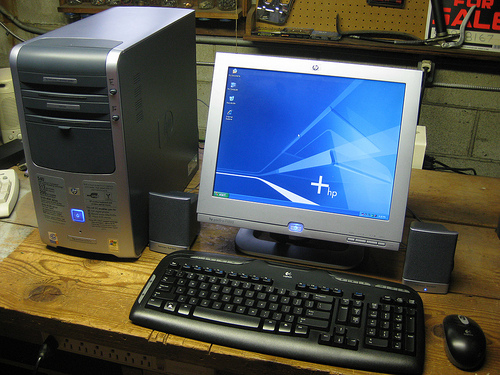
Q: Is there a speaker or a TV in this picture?
A: Yes, there is a speaker.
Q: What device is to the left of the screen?
A: The device is a speaker.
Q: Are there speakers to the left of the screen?
A: Yes, there is a speaker to the left of the screen.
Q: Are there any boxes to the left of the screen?
A: No, there is a speaker to the left of the screen.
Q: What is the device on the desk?
A: The device is a speaker.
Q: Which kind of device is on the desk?
A: The device is a speaker.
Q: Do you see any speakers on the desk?
A: Yes, there is a speaker on the desk.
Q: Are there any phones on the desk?
A: No, there is a speaker on the desk.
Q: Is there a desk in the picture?
A: Yes, there is a desk.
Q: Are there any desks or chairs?
A: Yes, there is a desk.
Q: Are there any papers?
A: No, there are no papers.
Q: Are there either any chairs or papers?
A: No, there are no papers or chairs.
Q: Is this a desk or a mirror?
A: This is a desk.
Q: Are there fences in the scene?
A: No, there are no fences.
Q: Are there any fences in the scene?
A: No, there are no fences.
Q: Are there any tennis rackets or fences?
A: No, there are no fences or tennis rackets.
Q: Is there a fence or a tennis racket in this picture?
A: No, there are no fences or rackets.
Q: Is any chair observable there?
A: No, there are no chairs.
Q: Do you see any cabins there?
A: No, there are no cabins.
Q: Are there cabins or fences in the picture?
A: No, there are no cabins or fences.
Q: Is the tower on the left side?
A: Yes, the tower is on the left of the image.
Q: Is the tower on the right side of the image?
A: No, the tower is on the left of the image.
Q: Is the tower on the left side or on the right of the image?
A: The tower is on the left of the image.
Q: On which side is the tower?
A: The tower is on the left of the image.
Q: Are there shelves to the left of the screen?
A: No, there is a tower to the left of the screen.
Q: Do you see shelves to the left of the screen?
A: No, there is a tower to the left of the screen.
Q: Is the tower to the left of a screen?
A: Yes, the tower is to the left of a screen.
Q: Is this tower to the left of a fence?
A: No, the tower is to the left of a screen.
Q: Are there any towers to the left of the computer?
A: Yes, there is a tower to the left of the computer.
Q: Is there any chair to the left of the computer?
A: No, there is a tower to the left of the computer.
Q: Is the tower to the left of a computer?
A: Yes, the tower is to the left of a computer.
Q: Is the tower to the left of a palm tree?
A: No, the tower is to the left of a computer.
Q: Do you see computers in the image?
A: Yes, there is a computer.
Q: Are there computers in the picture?
A: Yes, there is a computer.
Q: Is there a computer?
A: Yes, there is a computer.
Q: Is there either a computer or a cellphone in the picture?
A: Yes, there is a computer.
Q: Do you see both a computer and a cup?
A: No, there is a computer but no cups.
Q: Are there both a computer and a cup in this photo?
A: No, there is a computer but no cups.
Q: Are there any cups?
A: No, there are no cups.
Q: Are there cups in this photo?
A: No, there are no cups.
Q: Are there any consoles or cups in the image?
A: No, there are no cups or consoles.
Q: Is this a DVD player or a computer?
A: This is a computer.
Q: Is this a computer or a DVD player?
A: This is a computer.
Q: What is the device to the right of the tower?
A: The device is a computer.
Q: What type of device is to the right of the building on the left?
A: The device is a computer.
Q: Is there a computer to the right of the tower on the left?
A: Yes, there is a computer to the right of the tower.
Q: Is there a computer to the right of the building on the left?
A: Yes, there is a computer to the right of the tower.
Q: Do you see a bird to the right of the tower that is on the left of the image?
A: No, there is a computer to the right of the tower.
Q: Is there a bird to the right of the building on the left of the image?
A: No, there is a computer to the right of the tower.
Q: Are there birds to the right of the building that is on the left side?
A: No, there is a computer to the right of the tower.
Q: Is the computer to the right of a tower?
A: Yes, the computer is to the right of a tower.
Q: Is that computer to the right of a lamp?
A: No, the computer is to the right of a tower.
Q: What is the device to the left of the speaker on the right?
A: The device is a computer.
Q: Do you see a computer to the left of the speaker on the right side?
A: Yes, there is a computer to the left of the speaker.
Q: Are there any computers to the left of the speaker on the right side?
A: Yes, there is a computer to the left of the speaker.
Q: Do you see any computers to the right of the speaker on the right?
A: No, the computer is to the left of the speaker.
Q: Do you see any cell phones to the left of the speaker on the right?
A: No, there is a computer to the left of the speaker.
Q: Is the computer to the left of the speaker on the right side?
A: Yes, the computer is to the left of the speaker.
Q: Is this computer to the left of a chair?
A: No, the computer is to the left of the speaker.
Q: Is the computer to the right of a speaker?
A: No, the computer is to the left of a speaker.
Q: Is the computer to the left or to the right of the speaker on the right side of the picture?
A: The computer is to the left of the speaker.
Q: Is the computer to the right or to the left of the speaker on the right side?
A: The computer is to the left of the speaker.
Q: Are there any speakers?
A: Yes, there is a speaker.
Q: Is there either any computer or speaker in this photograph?
A: Yes, there is a speaker.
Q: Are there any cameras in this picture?
A: No, there are no cameras.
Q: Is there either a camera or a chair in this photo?
A: No, there are no cameras or chairs.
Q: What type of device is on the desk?
A: The device is a speaker.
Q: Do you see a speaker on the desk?
A: Yes, there is a speaker on the desk.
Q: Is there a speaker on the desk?
A: Yes, there is a speaker on the desk.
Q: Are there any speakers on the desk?
A: Yes, there is a speaker on the desk.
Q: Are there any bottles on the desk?
A: No, there is a speaker on the desk.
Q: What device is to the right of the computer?
A: The device is a speaker.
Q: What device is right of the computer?
A: The device is a speaker.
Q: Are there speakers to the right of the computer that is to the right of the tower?
A: Yes, there is a speaker to the right of the computer.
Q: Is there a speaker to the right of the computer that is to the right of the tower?
A: Yes, there is a speaker to the right of the computer.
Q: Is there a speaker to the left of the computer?
A: No, the speaker is to the right of the computer.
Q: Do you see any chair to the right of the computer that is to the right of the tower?
A: No, there is a speaker to the right of the computer.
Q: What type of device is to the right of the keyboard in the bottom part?
A: The device is a speaker.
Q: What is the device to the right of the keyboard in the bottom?
A: The device is a speaker.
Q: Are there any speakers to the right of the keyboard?
A: Yes, there is a speaker to the right of the keyboard.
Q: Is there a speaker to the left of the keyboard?
A: No, the speaker is to the right of the keyboard.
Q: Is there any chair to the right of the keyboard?
A: No, there is a speaker to the right of the keyboard.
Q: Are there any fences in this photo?
A: No, there are no fences.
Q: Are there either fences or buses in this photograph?
A: No, there are no fences or buses.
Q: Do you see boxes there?
A: No, there are no boxes.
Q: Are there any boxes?
A: No, there are no boxes.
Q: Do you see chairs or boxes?
A: No, there are no boxes or chairs.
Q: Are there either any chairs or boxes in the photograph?
A: No, there are no boxes or chairs.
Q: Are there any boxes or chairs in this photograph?
A: No, there are no boxes or chairs.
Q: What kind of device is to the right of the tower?
A: The device is a screen.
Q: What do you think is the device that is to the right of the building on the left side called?
A: The device is a screen.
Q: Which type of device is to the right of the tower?
A: The device is a screen.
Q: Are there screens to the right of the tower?
A: Yes, there is a screen to the right of the tower.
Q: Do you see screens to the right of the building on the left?
A: Yes, there is a screen to the right of the tower.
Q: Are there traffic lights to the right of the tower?
A: No, there is a screen to the right of the tower.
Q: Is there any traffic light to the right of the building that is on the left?
A: No, there is a screen to the right of the tower.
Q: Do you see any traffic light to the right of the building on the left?
A: No, there is a screen to the right of the tower.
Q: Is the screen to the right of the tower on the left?
A: Yes, the screen is to the right of the tower.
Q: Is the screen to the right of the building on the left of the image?
A: Yes, the screen is to the right of the tower.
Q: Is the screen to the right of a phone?
A: No, the screen is to the right of the tower.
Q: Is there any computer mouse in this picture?
A: Yes, there is a computer mouse.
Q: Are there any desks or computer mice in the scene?
A: Yes, there is a computer mouse.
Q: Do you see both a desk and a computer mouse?
A: Yes, there are both a computer mouse and a desk.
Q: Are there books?
A: No, there are no books.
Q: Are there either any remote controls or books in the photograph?
A: No, there are no books or remote controls.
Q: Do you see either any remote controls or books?
A: No, there are no books or remote controls.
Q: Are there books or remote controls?
A: No, there are no books or remote controls.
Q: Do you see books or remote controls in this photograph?
A: No, there are no books or remote controls.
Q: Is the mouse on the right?
A: Yes, the mouse is on the right of the image.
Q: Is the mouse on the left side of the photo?
A: No, the mouse is on the right of the image.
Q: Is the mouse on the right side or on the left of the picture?
A: The mouse is on the right of the image.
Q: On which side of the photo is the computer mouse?
A: The computer mouse is on the right of the image.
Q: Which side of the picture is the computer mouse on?
A: The computer mouse is on the right of the image.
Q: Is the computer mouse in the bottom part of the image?
A: Yes, the computer mouse is in the bottom of the image.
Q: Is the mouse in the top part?
A: No, the mouse is in the bottom of the image.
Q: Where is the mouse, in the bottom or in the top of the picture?
A: The mouse is in the bottom of the image.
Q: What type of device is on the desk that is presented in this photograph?
A: The device is a computer mouse.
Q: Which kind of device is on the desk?
A: The device is a computer mouse.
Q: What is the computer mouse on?
A: The computer mouse is on the desk.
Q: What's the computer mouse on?
A: The computer mouse is on the desk.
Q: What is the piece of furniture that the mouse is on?
A: The piece of furniture is a desk.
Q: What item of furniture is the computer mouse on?
A: The mouse is on the desk.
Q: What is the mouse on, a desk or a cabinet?
A: The mouse is on a desk.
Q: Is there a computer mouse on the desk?
A: Yes, there is a computer mouse on the desk.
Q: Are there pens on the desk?
A: No, there is a computer mouse on the desk.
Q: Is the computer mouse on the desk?
A: Yes, the computer mouse is on the desk.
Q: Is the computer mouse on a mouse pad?
A: No, the computer mouse is on the desk.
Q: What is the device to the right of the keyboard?
A: The device is a computer mouse.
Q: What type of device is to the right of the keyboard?
A: The device is a computer mouse.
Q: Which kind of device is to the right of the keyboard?
A: The device is a computer mouse.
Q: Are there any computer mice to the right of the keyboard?
A: Yes, there is a computer mouse to the right of the keyboard.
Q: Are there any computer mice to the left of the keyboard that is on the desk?
A: No, the computer mouse is to the right of the keyboard.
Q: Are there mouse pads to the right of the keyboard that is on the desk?
A: No, there is a computer mouse to the right of the keyboard.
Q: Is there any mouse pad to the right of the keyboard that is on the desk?
A: No, there is a computer mouse to the right of the keyboard.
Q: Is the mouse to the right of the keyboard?
A: Yes, the mouse is to the right of the keyboard.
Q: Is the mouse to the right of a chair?
A: No, the mouse is to the right of the keyboard.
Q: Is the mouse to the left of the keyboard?
A: No, the mouse is to the right of the keyboard.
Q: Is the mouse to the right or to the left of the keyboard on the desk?
A: The mouse is to the right of the keyboard.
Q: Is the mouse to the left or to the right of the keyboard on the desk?
A: The mouse is to the right of the keyboard.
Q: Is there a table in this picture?
A: Yes, there is a table.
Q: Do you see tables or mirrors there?
A: Yes, there is a table.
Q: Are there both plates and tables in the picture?
A: No, there is a table but no plates.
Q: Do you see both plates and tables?
A: No, there is a table but no plates.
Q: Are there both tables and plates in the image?
A: No, there is a table but no plates.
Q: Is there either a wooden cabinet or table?
A: Yes, there is a wood table.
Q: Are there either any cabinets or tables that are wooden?
A: Yes, the table is wooden.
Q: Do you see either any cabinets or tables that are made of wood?
A: Yes, the table is made of wood.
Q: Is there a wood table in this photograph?
A: Yes, there is a wood table.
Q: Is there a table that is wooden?
A: Yes, there is a table that is wooden.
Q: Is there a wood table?
A: Yes, there is a table that is made of wood.